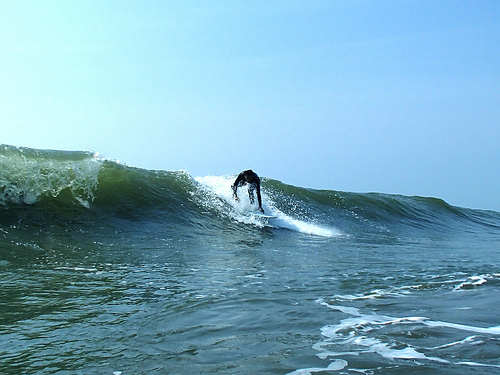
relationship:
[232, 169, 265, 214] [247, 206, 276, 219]
man on surfboard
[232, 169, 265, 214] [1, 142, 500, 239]
man surfing on wave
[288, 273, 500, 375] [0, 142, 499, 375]
foam on water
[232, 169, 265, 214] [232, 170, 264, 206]
man has wetsuit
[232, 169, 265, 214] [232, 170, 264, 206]
man in wetsuit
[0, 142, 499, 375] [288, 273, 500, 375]
water has foam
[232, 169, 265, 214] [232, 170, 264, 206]
man wearing wetsuit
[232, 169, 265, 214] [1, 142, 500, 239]
man on top of wave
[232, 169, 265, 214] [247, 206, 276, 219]
man standing on surfboard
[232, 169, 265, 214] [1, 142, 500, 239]
man going down wave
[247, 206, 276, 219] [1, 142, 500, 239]
surfboard on top of wave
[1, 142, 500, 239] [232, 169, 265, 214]
wave under man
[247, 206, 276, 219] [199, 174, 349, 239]
surfboard creating splash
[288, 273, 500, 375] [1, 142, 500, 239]
foam next to wave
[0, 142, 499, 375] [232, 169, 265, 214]
water under man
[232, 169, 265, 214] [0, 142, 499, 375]
man in water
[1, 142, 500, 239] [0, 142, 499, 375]
wave in water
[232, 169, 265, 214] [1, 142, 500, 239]
man riding wave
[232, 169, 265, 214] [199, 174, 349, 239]
man making splash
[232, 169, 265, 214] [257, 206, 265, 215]
man has hand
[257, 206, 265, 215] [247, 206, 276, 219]
hand touching surfboard